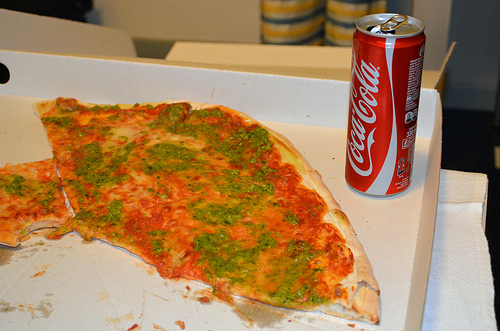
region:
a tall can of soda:
[332, 5, 437, 206]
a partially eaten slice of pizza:
[1, 152, 76, 269]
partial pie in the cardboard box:
[60, 61, 387, 321]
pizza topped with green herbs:
[75, 105, 345, 290]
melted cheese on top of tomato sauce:
[105, 107, 275, 247]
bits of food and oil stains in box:
[10, 251, 290, 326]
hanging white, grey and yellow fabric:
[250, 2, 395, 47]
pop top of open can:
[350, 10, 432, 42]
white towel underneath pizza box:
[395, 140, 491, 325]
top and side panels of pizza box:
[37, 3, 337, 84]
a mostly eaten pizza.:
[30, 68, 384, 328]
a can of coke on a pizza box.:
[335, 8, 443, 203]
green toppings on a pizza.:
[276, 244, 313, 295]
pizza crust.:
[323, 203, 378, 324]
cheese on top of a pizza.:
[113, 113, 148, 149]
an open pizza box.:
[0, 0, 451, 329]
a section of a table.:
[414, 170, 495, 329]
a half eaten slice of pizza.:
[0, 157, 70, 256]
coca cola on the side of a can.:
[338, 48, 383, 179]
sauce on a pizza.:
[113, 211, 168, 268]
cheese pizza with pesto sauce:
[42, 71, 314, 274]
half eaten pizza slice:
[3, 156, 64, 243]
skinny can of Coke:
[341, 1, 439, 201]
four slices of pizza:
[67, 88, 356, 315]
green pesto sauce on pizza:
[215, 123, 275, 183]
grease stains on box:
[188, 288, 294, 329]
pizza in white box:
[32, 59, 327, 281]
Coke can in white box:
[352, 21, 463, 248]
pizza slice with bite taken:
[4, 189, 84, 281]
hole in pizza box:
[3, 63, 28, 90]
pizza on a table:
[26, 83, 402, 328]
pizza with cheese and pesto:
[15, 78, 350, 329]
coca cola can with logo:
[323, 2, 438, 207]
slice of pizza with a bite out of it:
[2, 150, 82, 256]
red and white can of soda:
[341, 4, 436, 216]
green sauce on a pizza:
[27, 91, 297, 283]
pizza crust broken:
[308, 186, 387, 326]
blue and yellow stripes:
[255, 0, 399, 55]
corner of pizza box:
[421, 123, 498, 225]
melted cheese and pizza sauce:
[124, 190, 191, 246]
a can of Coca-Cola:
[345, 11, 422, 194]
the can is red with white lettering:
[345, 12, 422, 195]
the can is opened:
[360, 7, 425, 43]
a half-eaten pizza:
[2, 77, 364, 326]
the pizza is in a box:
[7, 7, 457, 326]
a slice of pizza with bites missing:
[3, 155, 70, 257]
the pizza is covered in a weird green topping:
[130, 118, 314, 255]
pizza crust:
[297, 159, 379, 328]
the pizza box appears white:
[16, 28, 348, 144]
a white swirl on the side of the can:
[362, 32, 403, 200]